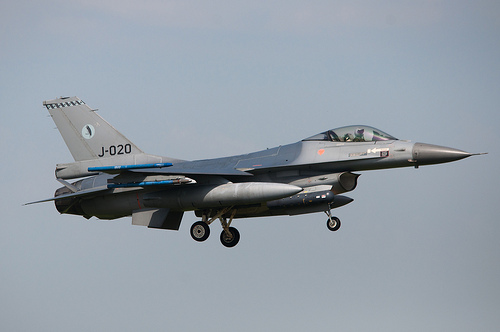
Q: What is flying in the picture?
A: A jet.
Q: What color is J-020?
A: Black.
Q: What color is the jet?
A: Gray.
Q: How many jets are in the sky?
A: One.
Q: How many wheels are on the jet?
A: 3.